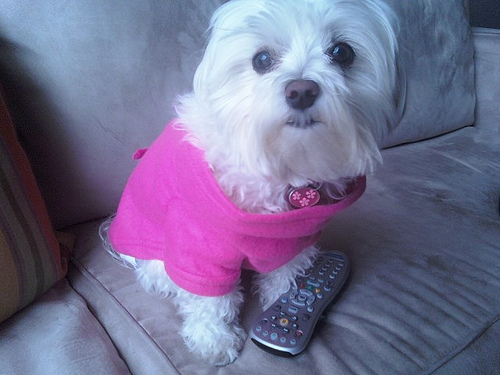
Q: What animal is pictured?
A: Dog.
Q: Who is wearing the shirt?
A: The dog.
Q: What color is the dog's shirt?
A: Pink.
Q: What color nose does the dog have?
A: Black.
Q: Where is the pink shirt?
A: On the dog.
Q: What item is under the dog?
A: TV Controller.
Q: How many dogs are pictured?
A: One.